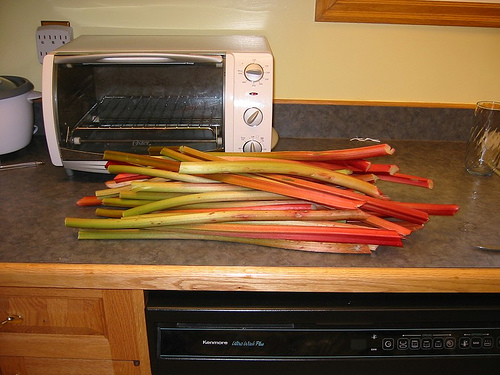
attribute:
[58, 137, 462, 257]
sticks — red, orange, green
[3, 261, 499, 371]
drawer —  wood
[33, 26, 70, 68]
outlet — six plug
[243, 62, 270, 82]
knob —  oven's,  3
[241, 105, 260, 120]
knob —  oven's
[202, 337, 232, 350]
kenmore — white, word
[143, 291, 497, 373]
dishwasher — black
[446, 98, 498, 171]
glass —  empty,  clear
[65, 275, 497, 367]
dishwasher —  black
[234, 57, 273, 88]
knob — at heat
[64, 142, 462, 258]
rhubarb — green, red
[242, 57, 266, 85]
knob — silver, top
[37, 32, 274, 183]
toaster oven — white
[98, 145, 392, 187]
stalks —  red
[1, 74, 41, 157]
pot —  crock,  white,  small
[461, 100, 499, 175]
glass —  of water,  empty, clear , upside down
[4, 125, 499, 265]
counter —  marbled,  brown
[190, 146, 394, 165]
stick — vegetable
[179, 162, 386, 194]
stick — vegetable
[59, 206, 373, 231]
stick — vegetable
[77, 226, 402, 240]
stick — vegetable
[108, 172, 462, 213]
stick — vegetable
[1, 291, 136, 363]
drawer —  brown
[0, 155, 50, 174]
pen —  black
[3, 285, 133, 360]
drawer — wooden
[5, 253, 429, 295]
counter — brown, part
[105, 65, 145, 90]
cooker —  black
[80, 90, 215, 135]
rack — metal 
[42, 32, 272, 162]
oven —  closed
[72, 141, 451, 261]
items — many colorful 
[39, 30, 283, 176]
oven — toaster, empty